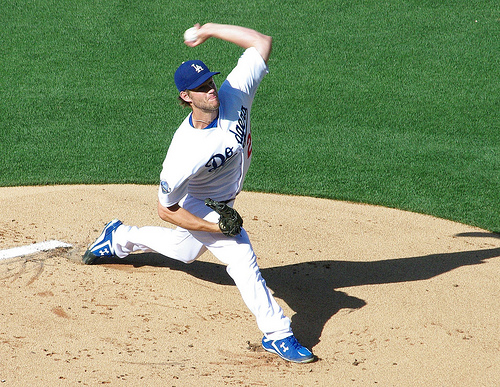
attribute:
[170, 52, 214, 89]
hat — blue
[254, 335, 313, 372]
shoe — blue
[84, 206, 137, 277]
shoe — blue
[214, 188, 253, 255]
glove — black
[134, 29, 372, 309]
man — white, playing, pitching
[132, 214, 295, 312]
pants — white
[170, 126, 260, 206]
shirt — white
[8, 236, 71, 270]
base — white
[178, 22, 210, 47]
ball — white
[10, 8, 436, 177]
grass — green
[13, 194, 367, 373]
sand — brown